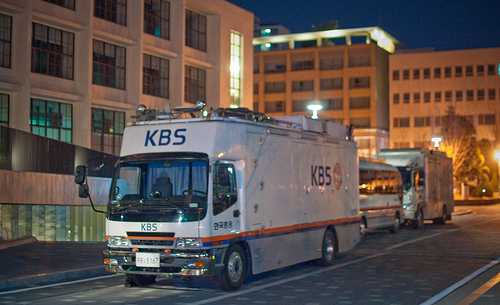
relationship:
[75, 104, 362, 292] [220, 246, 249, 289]
vehicule has front tire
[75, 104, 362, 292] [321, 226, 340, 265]
vehicule has left rear tire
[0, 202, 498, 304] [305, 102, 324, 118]
street has street light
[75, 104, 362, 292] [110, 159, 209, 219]
vehicule has windshield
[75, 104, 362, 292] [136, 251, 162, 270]
vehicule has license plate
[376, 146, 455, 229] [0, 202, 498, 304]
truck driving down street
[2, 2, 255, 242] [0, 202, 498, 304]
building near street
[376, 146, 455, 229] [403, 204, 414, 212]
truck has headlight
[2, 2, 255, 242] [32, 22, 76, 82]
building has window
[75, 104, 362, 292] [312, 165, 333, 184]
vehicule has logo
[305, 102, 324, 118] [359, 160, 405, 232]
street light above bus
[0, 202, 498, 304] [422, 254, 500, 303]
street has line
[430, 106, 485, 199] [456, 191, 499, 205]
tree on top of sidewalk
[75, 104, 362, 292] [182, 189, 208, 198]
vehicule has wheel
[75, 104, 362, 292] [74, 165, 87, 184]
vehicule has side mirror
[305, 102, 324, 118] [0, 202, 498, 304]
street light on top of street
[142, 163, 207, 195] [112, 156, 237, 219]
curtain behind driving compartment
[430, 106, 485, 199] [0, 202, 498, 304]
tree on top of street